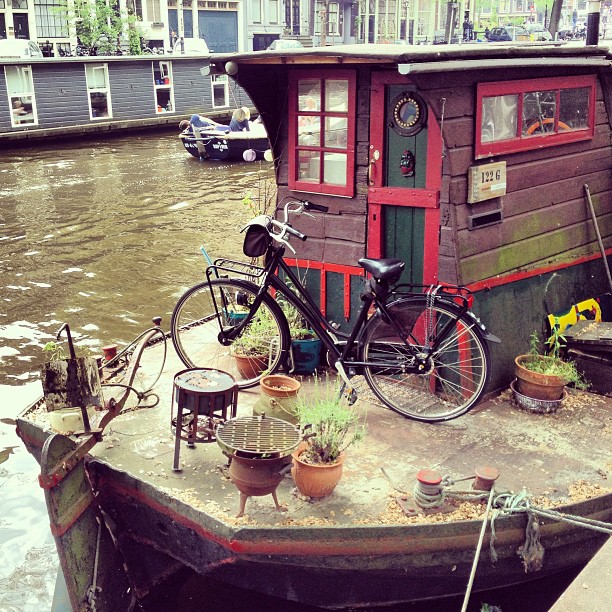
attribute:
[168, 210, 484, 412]
bicycle — black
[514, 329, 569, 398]
pottedplant — small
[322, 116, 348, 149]
glass — clear, clean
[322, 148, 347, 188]
glass — clean, clear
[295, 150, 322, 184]
glass — clean, clear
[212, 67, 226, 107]
glass — clear, clean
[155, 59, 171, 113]
glass — clean, clear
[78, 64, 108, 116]
glass — clear, clean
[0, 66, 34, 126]
glass — clean, clear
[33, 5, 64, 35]
glass — clear, clean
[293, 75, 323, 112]
glass — clean, clear